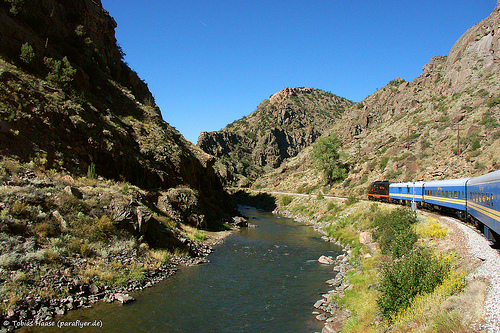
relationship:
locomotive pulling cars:
[361, 178, 389, 201] [389, 167, 500, 248]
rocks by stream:
[318, 246, 352, 314] [49, 199, 334, 333]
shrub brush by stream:
[372, 210, 447, 310] [49, 199, 334, 333]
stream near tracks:
[49, 199, 334, 333] [312, 194, 452, 221]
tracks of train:
[312, 194, 452, 221] [367, 170, 499, 246]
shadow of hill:
[230, 185, 283, 213] [1, 1, 231, 216]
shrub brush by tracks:
[372, 210, 447, 310] [312, 194, 452, 221]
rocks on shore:
[318, 246, 352, 314] [268, 195, 447, 333]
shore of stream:
[268, 195, 447, 333] [49, 199, 334, 333]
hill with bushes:
[1, 1, 231, 216] [16, 43, 98, 111]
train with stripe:
[367, 170, 499, 246] [387, 191, 499, 218]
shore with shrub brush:
[268, 195, 447, 333] [372, 210, 447, 310]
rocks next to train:
[318, 246, 352, 314] [367, 170, 499, 246]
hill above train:
[1, 1, 231, 216] [367, 170, 499, 246]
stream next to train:
[49, 199, 334, 333] [367, 170, 499, 246]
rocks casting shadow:
[180, 123, 225, 181] [230, 185, 283, 213]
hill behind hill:
[192, 69, 360, 170] [1, 1, 231, 216]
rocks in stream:
[318, 246, 352, 314] [49, 199, 334, 333]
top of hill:
[260, 85, 338, 113] [192, 69, 360, 170]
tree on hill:
[312, 133, 344, 186] [249, 50, 498, 182]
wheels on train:
[455, 211, 478, 227] [367, 170, 499, 246]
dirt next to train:
[439, 225, 469, 260] [367, 170, 499, 246]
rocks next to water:
[318, 246, 352, 314] [238, 208, 310, 271]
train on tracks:
[367, 170, 499, 246] [312, 194, 452, 221]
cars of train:
[389, 167, 500, 248] [367, 170, 499, 246]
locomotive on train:
[361, 178, 389, 201] [367, 170, 499, 246]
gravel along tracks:
[472, 236, 499, 283] [312, 194, 452, 221]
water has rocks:
[238, 208, 310, 271] [318, 246, 352, 314]